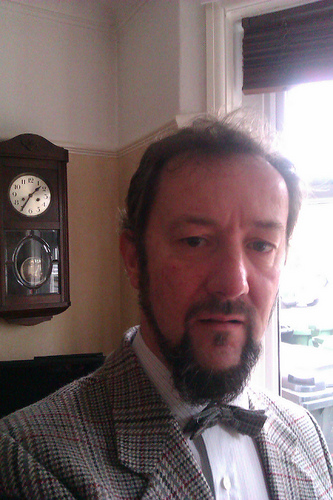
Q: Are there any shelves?
A: No, there are no shelves.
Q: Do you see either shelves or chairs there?
A: No, there are no shelves or chairs.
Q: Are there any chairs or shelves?
A: No, there are no shelves or chairs.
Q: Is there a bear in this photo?
A: No, there are no bears.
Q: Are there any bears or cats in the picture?
A: No, there are no bears or cats.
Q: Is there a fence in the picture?
A: No, there are no fences.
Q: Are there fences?
A: No, there are no fences.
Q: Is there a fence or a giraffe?
A: No, there are no fences or giraffes.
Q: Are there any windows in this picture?
A: Yes, there is a window.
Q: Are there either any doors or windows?
A: Yes, there is a window.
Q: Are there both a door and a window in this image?
A: No, there is a window but no doors.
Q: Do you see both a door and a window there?
A: No, there is a window but no doors.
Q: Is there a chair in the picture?
A: No, there are no chairs.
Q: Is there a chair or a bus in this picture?
A: No, there are no chairs or buses.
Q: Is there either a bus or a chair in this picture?
A: No, there are no chairs or buses.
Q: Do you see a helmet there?
A: No, there are no helmets.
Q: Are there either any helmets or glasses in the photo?
A: No, there are no helmets or glasses.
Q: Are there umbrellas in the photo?
A: No, there are no umbrellas.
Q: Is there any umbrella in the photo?
A: No, there are no umbrellas.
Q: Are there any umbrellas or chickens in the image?
A: No, there are no umbrellas or chickens.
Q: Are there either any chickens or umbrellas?
A: No, there are no umbrellas or chickens.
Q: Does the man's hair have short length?
A: Yes, the hair is short.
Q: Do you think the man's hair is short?
A: Yes, the hair is short.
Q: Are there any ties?
A: Yes, there is a tie.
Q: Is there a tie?
A: Yes, there is a tie.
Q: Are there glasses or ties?
A: Yes, there is a tie.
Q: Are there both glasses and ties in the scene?
A: No, there is a tie but no glasses.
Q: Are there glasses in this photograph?
A: No, there are no glasses.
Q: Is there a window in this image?
A: Yes, there is a window.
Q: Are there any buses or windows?
A: Yes, there is a window.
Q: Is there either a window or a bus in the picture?
A: Yes, there is a window.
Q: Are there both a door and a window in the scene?
A: No, there is a window but no doors.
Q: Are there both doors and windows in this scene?
A: No, there is a window but no doors.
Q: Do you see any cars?
A: No, there are no cars.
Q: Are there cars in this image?
A: No, there are no cars.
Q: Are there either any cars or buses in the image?
A: No, there are no cars or buses.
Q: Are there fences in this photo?
A: No, there are no fences.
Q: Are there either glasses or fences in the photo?
A: No, there are no fences or glasses.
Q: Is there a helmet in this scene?
A: No, there are no helmets.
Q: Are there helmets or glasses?
A: No, there are no helmets or glasses.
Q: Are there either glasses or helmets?
A: No, there are no helmets or glasses.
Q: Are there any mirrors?
A: No, there are no mirrors.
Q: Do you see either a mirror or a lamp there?
A: No, there are no mirrors or lamps.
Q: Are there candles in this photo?
A: No, there are no candles.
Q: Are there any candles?
A: No, there are no candles.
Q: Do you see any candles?
A: No, there are no candles.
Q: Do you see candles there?
A: No, there are no candles.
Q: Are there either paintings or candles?
A: No, there are no candles or paintings.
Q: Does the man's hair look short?
A: Yes, the hair is short.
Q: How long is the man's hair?
A: The hair is short.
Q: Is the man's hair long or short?
A: The hair is short.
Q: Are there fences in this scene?
A: No, there are no fences.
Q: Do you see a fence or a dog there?
A: No, there are no fences or dogs.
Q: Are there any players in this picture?
A: No, there are no players.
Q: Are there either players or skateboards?
A: No, there are no players or skateboards.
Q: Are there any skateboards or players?
A: No, there are no players or skateboards.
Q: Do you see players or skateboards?
A: No, there are no players or skateboards.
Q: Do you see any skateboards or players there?
A: No, there are no players or skateboards.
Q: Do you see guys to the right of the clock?
A: Yes, there is a guy to the right of the clock.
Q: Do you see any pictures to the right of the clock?
A: No, there is a guy to the right of the clock.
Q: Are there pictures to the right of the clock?
A: No, there is a guy to the right of the clock.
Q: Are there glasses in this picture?
A: No, there are no glasses.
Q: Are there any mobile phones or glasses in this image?
A: No, there are no glasses or mobile phones.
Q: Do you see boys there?
A: No, there are no boys.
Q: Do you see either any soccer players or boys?
A: No, there are no boys or soccer players.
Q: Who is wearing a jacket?
A: The man is wearing a jacket.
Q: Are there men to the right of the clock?
A: Yes, there is a man to the right of the clock.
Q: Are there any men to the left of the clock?
A: No, the man is to the right of the clock.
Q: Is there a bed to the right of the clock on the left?
A: No, there is a man to the right of the clock.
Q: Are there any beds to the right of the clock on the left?
A: No, there is a man to the right of the clock.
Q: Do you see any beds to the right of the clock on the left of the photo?
A: No, there is a man to the right of the clock.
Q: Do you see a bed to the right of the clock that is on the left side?
A: No, there is a man to the right of the clock.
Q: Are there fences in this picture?
A: No, there are no fences.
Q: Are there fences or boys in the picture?
A: No, there are no fences or boys.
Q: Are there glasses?
A: No, there are no glasses.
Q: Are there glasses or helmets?
A: No, there are no glasses or helmets.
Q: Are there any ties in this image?
A: Yes, there is a tie.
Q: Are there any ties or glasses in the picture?
A: Yes, there is a tie.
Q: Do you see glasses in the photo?
A: No, there are no glasses.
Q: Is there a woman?
A: No, there are no women.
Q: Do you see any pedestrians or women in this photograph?
A: No, there are no women or pedestrians.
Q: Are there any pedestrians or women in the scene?
A: No, there are no women or pedestrians.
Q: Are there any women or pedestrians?
A: No, there are no women or pedestrians.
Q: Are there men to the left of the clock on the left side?
A: No, the man is to the right of the clock.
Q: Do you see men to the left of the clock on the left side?
A: No, the man is to the right of the clock.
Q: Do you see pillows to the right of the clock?
A: No, there is a man to the right of the clock.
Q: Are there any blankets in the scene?
A: No, there are no blankets.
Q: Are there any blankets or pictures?
A: No, there are no blankets or pictures.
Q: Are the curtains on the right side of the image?
A: Yes, the curtains are on the right of the image.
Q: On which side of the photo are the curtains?
A: The curtains are on the right of the image.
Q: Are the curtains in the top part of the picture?
A: Yes, the curtains are in the top of the image.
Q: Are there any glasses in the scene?
A: No, there are no glasses.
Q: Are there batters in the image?
A: No, there are no batters.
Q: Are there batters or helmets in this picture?
A: No, there are no batters or helmets.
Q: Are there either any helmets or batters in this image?
A: No, there are no batters or helmets.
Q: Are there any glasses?
A: No, there are no glasses.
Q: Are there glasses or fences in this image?
A: No, there are no glasses or fences.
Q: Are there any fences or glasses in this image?
A: No, there are no glasses or fences.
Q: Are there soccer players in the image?
A: No, there are no soccer players.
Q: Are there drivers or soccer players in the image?
A: No, there are no soccer players or drivers.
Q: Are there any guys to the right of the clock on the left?
A: Yes, there is a guy to the right of the clock.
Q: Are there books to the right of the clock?
A: No, there is a guy to the right of the clock.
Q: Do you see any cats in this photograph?
A: No, there are no cats.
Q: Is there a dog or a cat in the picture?
A: No, there are no cats or dogs.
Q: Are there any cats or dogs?
A: No, there are no cats or dogs.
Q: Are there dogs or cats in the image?
A: No, there are no cats or dogs.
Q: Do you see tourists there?
A: No, there are no tourists.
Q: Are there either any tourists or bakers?
A: No, there are no tourists or bakers.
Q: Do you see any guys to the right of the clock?
A: Yes, there is a guy to the right of the clock.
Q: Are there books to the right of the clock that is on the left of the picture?
A: No, there is a guy to the right of the clock.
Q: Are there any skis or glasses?
A: No, there are no glasses or skis.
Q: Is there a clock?
A: Yes, there is a clock.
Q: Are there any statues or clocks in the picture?
A: Yes, there is a clock.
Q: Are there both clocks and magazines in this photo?
A: No, there is a clock but no magazines.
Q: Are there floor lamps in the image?
A: No, there are no floor lamps.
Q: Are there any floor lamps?
A: No, there are no floor lamps.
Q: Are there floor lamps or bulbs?
A: No, there are no floor lamps or bulbs.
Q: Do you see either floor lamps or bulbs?
A: No, there are no floor lamps or bulbs.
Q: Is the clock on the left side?
A: Yes, the clock is on the left of the image.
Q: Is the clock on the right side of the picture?
A: No, the clock is on the left of the image.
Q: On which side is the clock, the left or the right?
A: The clock is on the left of the image.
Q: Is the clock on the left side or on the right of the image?
A: The clock is on the left of the image.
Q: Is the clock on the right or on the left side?
A: The clock is on the left of the image.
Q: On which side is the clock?
A: The clock is on the left of the image.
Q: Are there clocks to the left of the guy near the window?
A: Yes, there is a clock to the left of the guy.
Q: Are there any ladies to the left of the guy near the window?
A: No, there is a clock to the left of the guy.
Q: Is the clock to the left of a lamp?
A: No, the clock is to the left of a guy.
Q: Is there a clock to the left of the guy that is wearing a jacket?
A: Yes, there is a clock to the left of the guy.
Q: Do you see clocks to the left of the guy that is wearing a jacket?
A: Yes, there is a clock to the left of the guy.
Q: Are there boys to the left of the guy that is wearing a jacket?
A: No, there is a clock to the left of the guy.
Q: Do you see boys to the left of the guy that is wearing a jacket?
A: No, there is a clock to the left of the guy.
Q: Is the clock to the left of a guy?
A: Yes, the clock is to the left of a guy.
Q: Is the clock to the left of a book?
A: No, the clock is to the left of a guy.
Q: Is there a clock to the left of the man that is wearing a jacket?
A: Yes, there is a clock to the left of the man.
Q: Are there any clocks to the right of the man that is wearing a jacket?
A: No, the clock is to the left of the man.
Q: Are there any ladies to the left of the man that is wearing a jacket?
A: No, there is a clock to the left of the man.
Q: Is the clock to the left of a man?
A: Yes, the clock is to the left of a man.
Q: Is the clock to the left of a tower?
A: No, the clock is to the left of a man.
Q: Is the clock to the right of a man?
A: No, the clock is to the left of a man.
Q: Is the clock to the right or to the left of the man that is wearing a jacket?
A: The clock is to the left of the man.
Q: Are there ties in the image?
A: Yes, there is a tie.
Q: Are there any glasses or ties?
A: Yes, there is a tie.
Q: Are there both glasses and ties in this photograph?
A: No, there is a tie but no glasses.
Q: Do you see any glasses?
A: No, there are no glasses.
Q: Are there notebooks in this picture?
A: No, there are no notebooks.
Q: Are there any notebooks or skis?
A: No, there are no notebooks or skis.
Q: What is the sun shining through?
A: The sun is shining through the window.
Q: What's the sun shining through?
A: The sun is shining through the window.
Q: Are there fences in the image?
A: No, there are no fences.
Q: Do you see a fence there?
A: No, there are no fences.